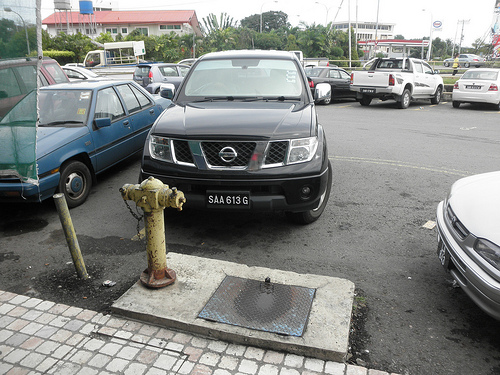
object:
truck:
[350, 58, 444, 109]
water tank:
[54, 0, 70, 9]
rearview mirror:
[314, 83, 331, 105]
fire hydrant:
[119, 176, 186, 287]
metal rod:
[52, 193, 91, 280]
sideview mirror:
[160, 83, 175, 99]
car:
[435, 171, 500, 321]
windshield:
[184, 59, 302, 97]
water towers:
[54, 0, 94, 35]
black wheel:
[58, 161, 91, 208]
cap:
[169, 187, 186, 210]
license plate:
[206, 190, 250, 209]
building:
[41, 11, 202, 44]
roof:
[42, 10, 201, 37]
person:
[452, 53, 462, 76]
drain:
[196, 275, 315, 336]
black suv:
[138, 51, 333, 223]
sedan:
[451, 68, 499, 110]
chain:
[123, 197, 147, 249]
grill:
[149, 137, 318, 172]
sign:
[433, 21, 442, 29]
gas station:
[358, 40, 437, 60]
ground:
[0, 98, 500, 375]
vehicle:
[0, 81, 173, 208]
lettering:
[209, 195, 248, 204]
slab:
[109, 251, 354, 363]